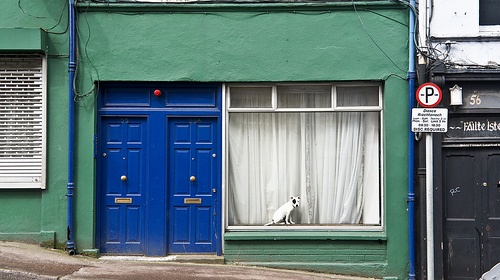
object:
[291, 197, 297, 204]
eye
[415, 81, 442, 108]
traffic sign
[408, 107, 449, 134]
traffic sign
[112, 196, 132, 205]
mail slot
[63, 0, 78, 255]
pole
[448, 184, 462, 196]
graffiti patch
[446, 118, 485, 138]
sign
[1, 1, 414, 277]
wall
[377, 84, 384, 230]
edge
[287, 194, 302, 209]
head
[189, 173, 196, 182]
handle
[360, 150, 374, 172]
handle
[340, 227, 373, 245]
edge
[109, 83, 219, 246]
doors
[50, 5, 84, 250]
pipe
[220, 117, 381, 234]
window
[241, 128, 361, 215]
curtains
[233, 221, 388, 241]
sill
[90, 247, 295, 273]
pavement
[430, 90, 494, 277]
doors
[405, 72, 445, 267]
pole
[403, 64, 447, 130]
sign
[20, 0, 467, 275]
buildings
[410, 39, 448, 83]
cords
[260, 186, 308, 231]
dog